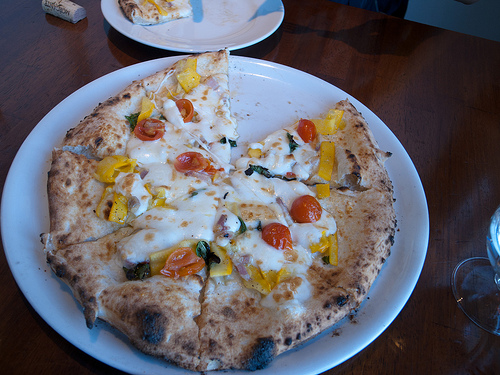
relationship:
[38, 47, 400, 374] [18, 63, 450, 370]
pizza on a plate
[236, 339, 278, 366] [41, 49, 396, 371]
area of pizza crust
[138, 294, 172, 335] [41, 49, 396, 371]
area of pizza crust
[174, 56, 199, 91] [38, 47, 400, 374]
yellow pepper on pizza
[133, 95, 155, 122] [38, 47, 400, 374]
yellow pepper on pizza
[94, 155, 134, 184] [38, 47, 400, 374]
yellow pepper on pizza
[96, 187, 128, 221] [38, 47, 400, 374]
yellow pepper on pizza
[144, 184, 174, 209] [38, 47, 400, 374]
yellow pepper on pizza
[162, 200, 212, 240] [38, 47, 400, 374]
cheese on a pizza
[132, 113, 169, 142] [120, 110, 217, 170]
tomato on cheese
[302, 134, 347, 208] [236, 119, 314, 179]
pepper on cheese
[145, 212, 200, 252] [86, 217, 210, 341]
mozzarella cheese on pizza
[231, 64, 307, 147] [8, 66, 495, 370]
crumbs on plate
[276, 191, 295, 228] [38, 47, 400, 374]
onion on pizza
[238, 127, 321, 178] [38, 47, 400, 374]
cheese on pizza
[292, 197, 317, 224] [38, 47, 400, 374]
tomato on pizza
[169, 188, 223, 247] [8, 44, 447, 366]
cheese on top of pizza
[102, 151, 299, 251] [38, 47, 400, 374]
cheese on top of pizza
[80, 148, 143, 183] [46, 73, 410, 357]
peppers on pizza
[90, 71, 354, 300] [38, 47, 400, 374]
cheese on top of pizza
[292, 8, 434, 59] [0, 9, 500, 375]
shadow on brown table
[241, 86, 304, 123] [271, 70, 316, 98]
crumbs on plate